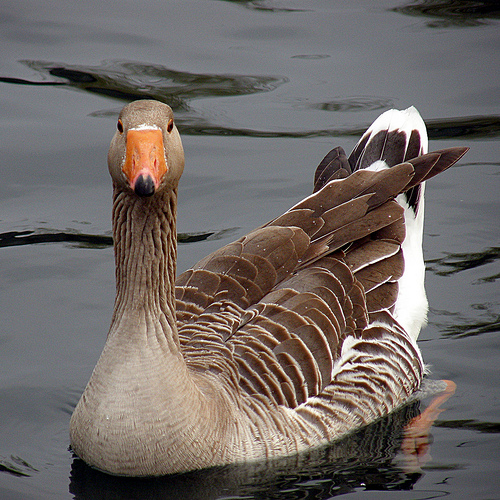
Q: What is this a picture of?
A: Duck.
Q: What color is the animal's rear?
A: White.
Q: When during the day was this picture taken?
A: Daytime.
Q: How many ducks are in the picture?
A: One.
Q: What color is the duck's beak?
A: Orange.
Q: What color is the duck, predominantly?
A: Brown.